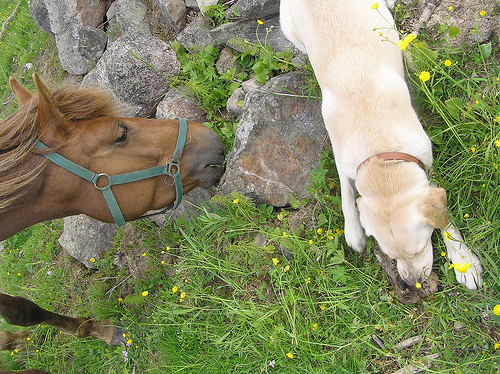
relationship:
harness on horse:
[25, 107, 198, 225] [5, 68, 242, 250]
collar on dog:
[348, 144, 429, 177] [274, 1, 493, 304]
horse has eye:
[5, 68, 242, 250] [104, 122, 137, 145]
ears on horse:
[4, 68, 72, 144] [5, 68, 242, 250]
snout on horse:
[172, 118, 231, 190] [5, 68, 242, 250]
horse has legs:
[5, 68, 242, 250] [0, 272, 132, 373]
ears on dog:
[351, 183, 454, 234] [274, 1, 493, 304]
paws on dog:
[343, 232, 492, 297] [274, 1, 493, 304]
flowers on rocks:
[387, 8, 499, 184] [25, 0, 493, 271]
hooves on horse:
[90, 310, 153, 355] [5, 68, 242, 250]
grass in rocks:
[163, 37, 307, 148] [25, 0, 493, 271]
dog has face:
[274, 1, 493, 304] [381, 243, 437, 287]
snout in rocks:
[172, 118, 231, 190] [25, 0, 493, 271]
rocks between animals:
[25, 0, 493, 271] [1, 0, 490, 352]